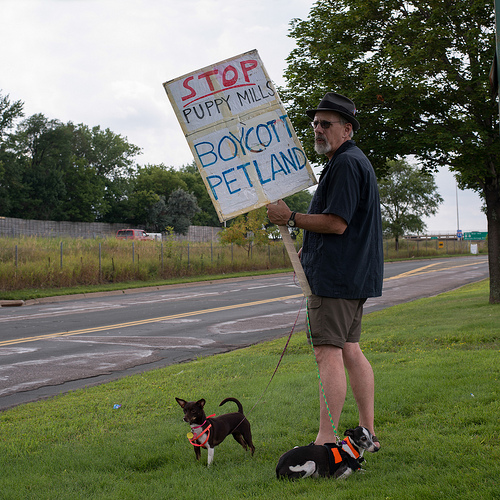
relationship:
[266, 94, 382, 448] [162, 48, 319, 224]
man holding sign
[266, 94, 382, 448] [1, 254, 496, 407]
man standing near road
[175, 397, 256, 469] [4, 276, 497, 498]
chihuahua standing in grass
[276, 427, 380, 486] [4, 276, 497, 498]
dog in grass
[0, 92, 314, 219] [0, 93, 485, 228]
trees in background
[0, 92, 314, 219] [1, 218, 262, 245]
wooded area has fence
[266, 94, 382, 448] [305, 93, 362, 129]
man wearing hat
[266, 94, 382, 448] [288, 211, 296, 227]
man wearing wristwatch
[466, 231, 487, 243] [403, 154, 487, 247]
road sign in distance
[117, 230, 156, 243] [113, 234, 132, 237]
truck has cover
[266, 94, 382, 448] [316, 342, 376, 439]
men's bare legs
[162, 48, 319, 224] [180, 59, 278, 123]
sign says stop puppy mills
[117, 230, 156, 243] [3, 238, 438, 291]
vehicle in field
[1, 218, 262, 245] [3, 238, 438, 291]
fence in field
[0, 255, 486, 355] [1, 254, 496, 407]
yellow strip in road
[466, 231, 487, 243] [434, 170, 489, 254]
sign in background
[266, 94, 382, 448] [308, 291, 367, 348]
man wearing shorts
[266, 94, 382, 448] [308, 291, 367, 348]
man in shorts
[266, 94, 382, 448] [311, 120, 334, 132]
man wearing glasses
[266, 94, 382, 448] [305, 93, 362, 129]
man in hat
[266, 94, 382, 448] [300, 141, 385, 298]
man in shirt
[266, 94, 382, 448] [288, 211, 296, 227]
man has watch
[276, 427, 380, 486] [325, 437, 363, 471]
dog wearing harness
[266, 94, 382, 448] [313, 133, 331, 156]
man has facial hair